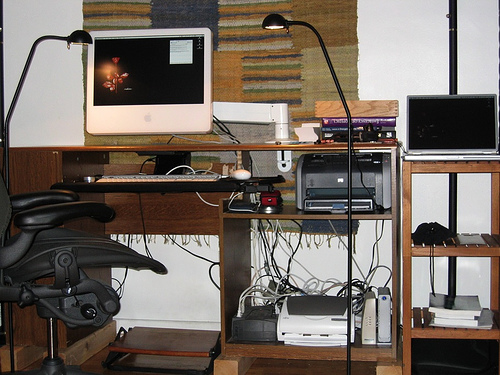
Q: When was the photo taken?
A: Daytime.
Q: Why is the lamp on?
A: To light the space.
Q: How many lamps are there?
A: Two.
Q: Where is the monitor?
A: On the desk.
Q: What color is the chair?
A: Black.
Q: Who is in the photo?
A: Nobody.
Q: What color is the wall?
A: White.